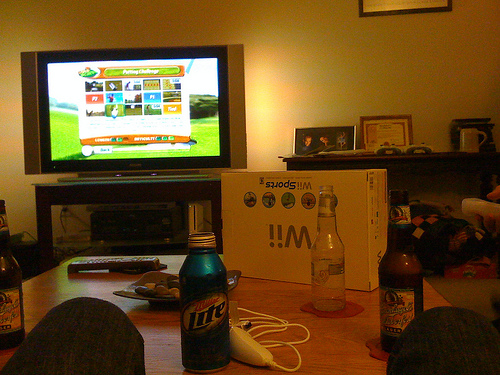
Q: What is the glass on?
A: The glass is on the table.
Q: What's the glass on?
A: The glass is on the table.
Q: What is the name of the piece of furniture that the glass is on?
A: The piece of furniture is a table.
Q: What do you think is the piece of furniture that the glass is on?
A: The piece of furniture is a table.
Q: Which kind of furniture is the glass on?
A: The glass is on the table.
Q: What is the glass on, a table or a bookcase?
A: The glass is on a table.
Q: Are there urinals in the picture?
A: No, there are no urinals.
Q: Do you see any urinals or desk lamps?
A: No, there are no urinals or desk lamps.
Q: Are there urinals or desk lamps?
A: No, there are no urinals or desk lamps.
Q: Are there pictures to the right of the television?
A: Yes, there is a picture to the right of the television.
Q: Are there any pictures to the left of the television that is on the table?
A: No, the picture is to the right of the television.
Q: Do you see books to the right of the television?
A: No, there is a picture to the right of the television.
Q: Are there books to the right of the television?
A: No, there is a picture to the right of the television.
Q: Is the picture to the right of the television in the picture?
A: Yes, the picture is to the right of the television.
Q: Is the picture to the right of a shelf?
A: No, the picture is to the right of the television.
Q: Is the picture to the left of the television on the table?
A: No, the picture is to the right of the TV.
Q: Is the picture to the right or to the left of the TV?
A: The picture is to the right of the TV.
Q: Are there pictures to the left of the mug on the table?
A: Yes, there is a picture to the left of the mug.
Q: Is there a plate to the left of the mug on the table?
A: No, there is a picture to the left of the mug.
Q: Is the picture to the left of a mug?
A: Yes, the picture is to the left of a mug.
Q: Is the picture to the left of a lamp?
A: No, the picture is to the left of a mug.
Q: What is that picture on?
A: The picture is on the table.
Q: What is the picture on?
A: The picture is on the table.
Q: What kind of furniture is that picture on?
A: The picture is on the table.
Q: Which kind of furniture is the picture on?
A: The picture is on the table.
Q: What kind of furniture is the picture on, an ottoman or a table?
A: The picture is on a table.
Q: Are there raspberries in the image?
A: No, there are no raspberries.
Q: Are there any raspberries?
A: No, there are no raspberries.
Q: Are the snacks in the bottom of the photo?
A: Yes, the snacks are in the bottom of the image.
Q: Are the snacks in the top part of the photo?
A: No, the snacks are in the bottom of the image.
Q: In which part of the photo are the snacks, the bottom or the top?
A: The snacks are in the bottom of the image.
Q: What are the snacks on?
A: The snacks are on the table.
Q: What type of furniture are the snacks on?
A: The snacks are on the table.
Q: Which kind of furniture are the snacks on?
A: The snacks are on the table.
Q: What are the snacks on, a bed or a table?
A: The snacks are on a table.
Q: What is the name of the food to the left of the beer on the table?
A: The food is snacks.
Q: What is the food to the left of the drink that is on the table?
A: The food is snacks.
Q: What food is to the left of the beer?
A: The food is snacks.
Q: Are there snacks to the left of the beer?
A: Yes, there are snacks to the left of the beer.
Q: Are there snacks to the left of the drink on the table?
A: Yes, there are snacks to the left of the beer.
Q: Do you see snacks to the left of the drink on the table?
A: Yes, there are snacks to the left of the beer.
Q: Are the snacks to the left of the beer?
A: Yes, the snacks are to the left of the beer.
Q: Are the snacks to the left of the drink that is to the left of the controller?
A: Yes, the snacks are to the left of the beer.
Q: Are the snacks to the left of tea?
A: No, the snacks are to the left of the beer.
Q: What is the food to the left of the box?
A: The food is snacks.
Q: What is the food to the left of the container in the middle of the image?
A: The food is snacks.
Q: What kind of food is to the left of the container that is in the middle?
A: The food is snacks.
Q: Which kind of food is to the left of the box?
A: The food is snacks.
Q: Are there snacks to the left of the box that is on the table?
A: Yes, there are snacks to the left of the box.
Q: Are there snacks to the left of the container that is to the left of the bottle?
A: Yes, there are snacks to the left of the box.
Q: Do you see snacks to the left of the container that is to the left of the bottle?
A: Yes, there are snacks to the left of the box.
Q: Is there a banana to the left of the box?
A: No, there are snacks to the left of the box.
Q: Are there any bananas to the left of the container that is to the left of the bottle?
A: No, there are snacks to the left of the box.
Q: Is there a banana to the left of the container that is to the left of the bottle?
A: No, there are snacks to the left of the box.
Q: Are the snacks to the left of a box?
A: Yes, the snacks are to the left of a box.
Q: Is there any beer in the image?
A: Yes, there is beer.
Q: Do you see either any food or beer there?
A: Yes, there is beer.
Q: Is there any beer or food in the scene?
A: Yes, there is beer.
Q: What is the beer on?
A: The beer is on the table.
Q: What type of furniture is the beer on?
A: The beer is on the table.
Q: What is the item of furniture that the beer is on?
A: The piece of furniture is a table.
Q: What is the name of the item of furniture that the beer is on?
A: The piece of furniture is a table.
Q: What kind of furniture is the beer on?
A: The beer is on the table.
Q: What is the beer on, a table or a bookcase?
A: The beer is on a table.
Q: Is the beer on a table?
A: Yes, the beer is on a table.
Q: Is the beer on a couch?
A: No, the beer is on a table.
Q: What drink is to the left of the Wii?
A: The drink is beer.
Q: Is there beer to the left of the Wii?
A: Yes, there is beer to the left of the Wii.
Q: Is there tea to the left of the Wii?
A: No, there is beer to the left of the Wii.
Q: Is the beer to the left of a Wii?
A: Yes, the beer is to the left of a Wii.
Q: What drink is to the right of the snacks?
A: The drink is beer.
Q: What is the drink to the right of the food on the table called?
A: The drink is beer.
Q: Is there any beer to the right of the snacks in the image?
A: Yes, there is beer to the right of the snacks.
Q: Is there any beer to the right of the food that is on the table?
A: Yes, there is beer to the right of the snacks.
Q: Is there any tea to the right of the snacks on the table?
A: No, there is beer to the right of the snacks.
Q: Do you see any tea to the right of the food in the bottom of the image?
A: No, there is beer to the right of the snacks.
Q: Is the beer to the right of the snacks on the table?
A: Yes, the beer is to the right of the snacks.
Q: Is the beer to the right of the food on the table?
A: Yes, the beer is to the right of the snacks.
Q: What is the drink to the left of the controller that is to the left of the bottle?
A: The drink is beer.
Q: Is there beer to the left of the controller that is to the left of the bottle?
A: Yes, there is beer to the left of the controller.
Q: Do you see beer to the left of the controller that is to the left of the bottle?
A: Yes, there is beer to the left of the controller.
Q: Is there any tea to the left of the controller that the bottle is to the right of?
A: No, there is beer to the left of the controller.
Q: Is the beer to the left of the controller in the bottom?
A: Yes, the beer is to the left of the controller.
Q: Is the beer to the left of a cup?
A: No, the beer is to the left of the controller.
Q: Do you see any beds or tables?
A: Yes, there is a table.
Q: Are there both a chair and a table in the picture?
A: No, there is a table but no chairs.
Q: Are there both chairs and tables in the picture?
A: No, there is a table but no chairs.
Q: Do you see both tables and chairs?
A: No, there is a table but no chairs.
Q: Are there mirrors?
A: No, there are no mirrors.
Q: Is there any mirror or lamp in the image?
A: No, there are no mirrors or lamps.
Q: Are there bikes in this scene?
A: No, there are no bikes.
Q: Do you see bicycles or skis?
A: No, there are no bicycles or skis.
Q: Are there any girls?
A: No, there are no girls.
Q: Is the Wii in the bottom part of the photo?
A: Yes, the Wii is in the bottom of the image.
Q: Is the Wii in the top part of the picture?
A: No, the Wii is in the bottom of the image.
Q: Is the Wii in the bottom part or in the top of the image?
A: The Wii is in the bottom of the image.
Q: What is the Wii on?
A: The Wii is on the table.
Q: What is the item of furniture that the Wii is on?
A: The piece of furniture is a table.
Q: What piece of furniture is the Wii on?
A: The Wii is on the table.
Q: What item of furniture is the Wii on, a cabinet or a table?
A: The Wii is on a table.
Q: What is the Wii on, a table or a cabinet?
A: The Wii is on a table.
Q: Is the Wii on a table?
A: Yes, the Wii is on a table.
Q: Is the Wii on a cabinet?
A: No, the Wii is on a table.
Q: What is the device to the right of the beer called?
A: The device is a Wii.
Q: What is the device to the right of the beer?
A: The device is a Wii.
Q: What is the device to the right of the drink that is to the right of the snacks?
A: The device is a Wii.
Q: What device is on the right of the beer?
A: The device is a Wii.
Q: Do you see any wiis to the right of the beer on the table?
A: Yes, there is a Wii to the right of the beer.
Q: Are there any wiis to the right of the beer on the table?
A: Yes, there is a Wii to the right of the beer.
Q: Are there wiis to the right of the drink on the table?
A: Yes, there is a Wii to the right of the beer.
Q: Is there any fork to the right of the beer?
A: No, there is a Wii to the right of the beer.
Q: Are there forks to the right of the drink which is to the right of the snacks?
A: No, there is a Wii to the right of the beer.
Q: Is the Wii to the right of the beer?
A: Yes, the Wii is to the right of the beer.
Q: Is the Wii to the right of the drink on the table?
A: Yes, the Wii is to the right of the beer.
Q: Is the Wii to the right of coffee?
A: No, the Wii is to the right of the beer.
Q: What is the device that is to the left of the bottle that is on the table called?
A: The device is a Wii.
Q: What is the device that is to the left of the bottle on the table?
A: The device is a Wii.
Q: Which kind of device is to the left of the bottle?
A: The device is a Wii.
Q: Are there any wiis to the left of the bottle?
A: Yes, there is a Wii to the left of the bottle.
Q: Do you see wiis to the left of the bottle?
A: Yes, there is a Wii to the left of the bottle.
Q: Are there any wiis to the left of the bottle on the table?
A: Yes, there is a Wii to the left of the bottle.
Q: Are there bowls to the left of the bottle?
A: No, there is a Wii to the left of the bottle.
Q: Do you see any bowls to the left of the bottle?
A: No, there is a Wii to the left of the bottle.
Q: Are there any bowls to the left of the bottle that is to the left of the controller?
A: No, there is a Wii to the left of the bottle.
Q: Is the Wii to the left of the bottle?
A: Yes, the Wii is to the left of the bottle.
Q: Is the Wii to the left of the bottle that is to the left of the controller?
A: Yes, the Wii is to the left of the bottle.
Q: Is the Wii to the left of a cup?
A: No, the Wii is to the left of the bottle.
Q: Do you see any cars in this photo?
A: No, there are no cars.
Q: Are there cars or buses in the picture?
A: No, there are no cars or buses.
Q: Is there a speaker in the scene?
A: No, there are no speakers.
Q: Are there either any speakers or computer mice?
A: No, there are no speakers or computer mice.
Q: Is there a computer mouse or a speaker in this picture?
A: No, there are no speakers or computer mice.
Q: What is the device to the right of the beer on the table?
A: The device is a controller.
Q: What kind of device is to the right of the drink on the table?
A: The device is a controller.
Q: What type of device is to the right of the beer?
A: The device is a controller.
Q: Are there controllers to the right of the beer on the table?
A: Yes, there is a controller to the right of the beer.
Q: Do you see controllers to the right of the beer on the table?
A: Yes, there is a controller to the right of the beer.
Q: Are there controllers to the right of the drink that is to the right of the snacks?
A: Yes, there is a controller to the right of the beer.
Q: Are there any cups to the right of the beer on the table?
A: No, there is a controller to the right of the beer.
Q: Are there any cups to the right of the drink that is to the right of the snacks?
A: No, there is a controller to the right of the beer.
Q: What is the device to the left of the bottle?
A: The device is a controller.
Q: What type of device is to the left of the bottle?
A: The device is a controller.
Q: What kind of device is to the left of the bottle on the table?
A: The device is a controller.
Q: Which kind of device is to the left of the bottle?
A: The device is a controller.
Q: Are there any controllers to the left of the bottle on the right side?
A: Yes, there is a controller to the left of the bottle.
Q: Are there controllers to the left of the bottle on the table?
A: Yes, there is a controller to the left of the bottle.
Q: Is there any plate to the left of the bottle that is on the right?
A: No, there is a controller to the left of the bottle.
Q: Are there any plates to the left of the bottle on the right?
A: No, there is a controller to the left of the bottle.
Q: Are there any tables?
A: Yes, there is a table.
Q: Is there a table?
A: Yes, there is a table.